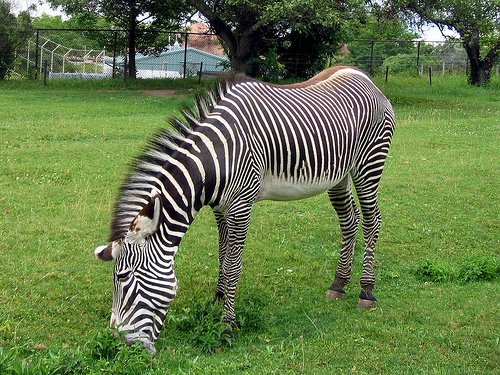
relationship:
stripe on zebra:
[267, 85, 316, 185] [92, 60, 396, 359]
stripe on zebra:
[119, 301, 164, 322] [92, 60, 396, 359]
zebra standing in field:
[92, 60, 396, 359] [2, 77, 484, 371]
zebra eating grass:
[92, 60, 396, 359] [2, 79, 484, 372]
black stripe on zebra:
[159, 175, 188, 210] [76, 65, 394, 334]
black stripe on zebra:
[196, 139, 218, 201] [102, 63, 395, 331]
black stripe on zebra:
[191, 124, 225, 211] [76, 65, 394, 334]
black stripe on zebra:
[259, 94, 283, 164] [92, 60, 396, 359]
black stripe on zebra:
[274, 115, 298, 170] [76, 65, 394, 334]